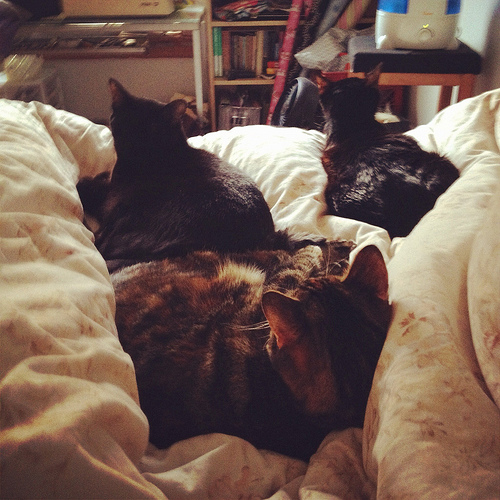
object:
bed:
[1, 89, 494, 498]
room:
[1, 89, 494, 499]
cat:
[113, 234, 390, 459]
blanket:
[2, 90, 497, 494]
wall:
[1, 14, 201, 121]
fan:
[272, 67, 319, 127]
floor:
[88, 112, 123, 139]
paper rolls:
[295, 21, 347, 76]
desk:
[10, 1, 220, 131]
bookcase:
[202, 2, 297, 126]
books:
[212, 32, 222, 77]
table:
[348, 34, 480, 111]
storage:
[0, 75, 68, 127]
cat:
[74, 73, 291, 261]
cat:
[307, 62, 461, 233]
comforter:
[381, 160, 498, 497]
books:
[230, 29, 242, 77]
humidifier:
[374, 13, 456, 47]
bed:
[189, 117, 328, 227]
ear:
[257, 286, 307, 345]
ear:
[345, 239, 389, 305]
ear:
[110, 75, 135, 108]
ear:
[313, 66, 332, 103]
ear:
[365, 63, 388, 91]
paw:
[80, 174, 107, 206]